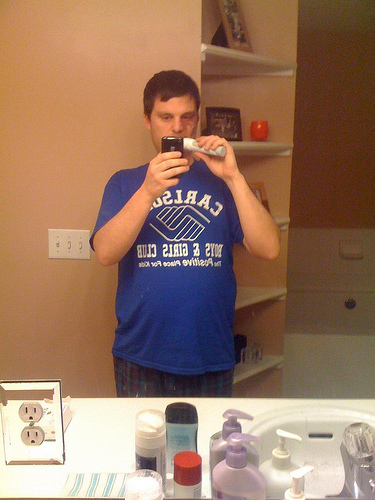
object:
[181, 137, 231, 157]
toothbrush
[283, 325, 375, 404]
tub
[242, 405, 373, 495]
dirty sink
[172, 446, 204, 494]
shaving cream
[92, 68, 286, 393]
man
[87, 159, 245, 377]
shirt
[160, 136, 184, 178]
cell phone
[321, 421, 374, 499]
faucet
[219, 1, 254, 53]
picture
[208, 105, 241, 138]
picture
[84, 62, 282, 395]
boy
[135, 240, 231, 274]
writing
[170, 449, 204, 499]
bottle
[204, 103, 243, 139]
frane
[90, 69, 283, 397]
bathtub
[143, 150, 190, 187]
hand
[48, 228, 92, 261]
light switches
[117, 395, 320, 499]
toiletries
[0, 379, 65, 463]
outlet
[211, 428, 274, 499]
lotion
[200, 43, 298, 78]
shelf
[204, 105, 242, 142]
picture frame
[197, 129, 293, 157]
shelf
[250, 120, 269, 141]
candle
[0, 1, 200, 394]
wall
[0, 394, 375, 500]
counter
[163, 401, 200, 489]
bottles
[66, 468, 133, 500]
towel counter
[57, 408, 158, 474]
dish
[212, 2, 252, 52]
frame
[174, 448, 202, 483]
cap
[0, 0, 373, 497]
mirror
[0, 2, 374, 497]
bathroom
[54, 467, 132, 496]
towel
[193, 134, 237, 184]
hand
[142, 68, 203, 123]
hair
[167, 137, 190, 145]
teeth